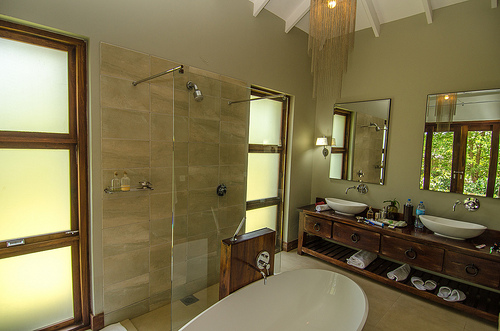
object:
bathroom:
[2, 2, 498, 327]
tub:
[171, 267, 368, 331]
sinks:
[323, 196, 370, 217]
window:
[241, 152, 281, 200]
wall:
[87, 0, 324, 328]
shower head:
[183, 81, 207, 103]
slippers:
[444, 290, 467, 301]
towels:
[346, 248, 377, 269]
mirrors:
[321, 98, 388, 184]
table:
[296, 199, 500, 330]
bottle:
[111, 170, 121, 191]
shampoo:
[111, 169, 121, 191]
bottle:
[121, 171, 131, 192]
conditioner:
[120, 170, 131, 192]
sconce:
[315, 137, 329, 159]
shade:
[321, 148, 328, 158]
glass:
[245, 94, 283, 145]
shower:
[108, 64, 368, 331]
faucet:
[343, 185, 368, 196]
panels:
[101, 103, 149, 139]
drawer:
[380, 233, 445, 272]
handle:
[404, 249, 417, 260]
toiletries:
[403, 197, 414, 227]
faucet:
[255, 246, 272, 286]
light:
[299, 3, 348, 102]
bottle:
[414, 197, 426, 229]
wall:
[309, 8, 500, 228]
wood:
[448, 253, 455, 258]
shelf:
[305, 239, 336, 257]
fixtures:
[216, 182, 228, 197]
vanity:
[330, 221, 383, 254]